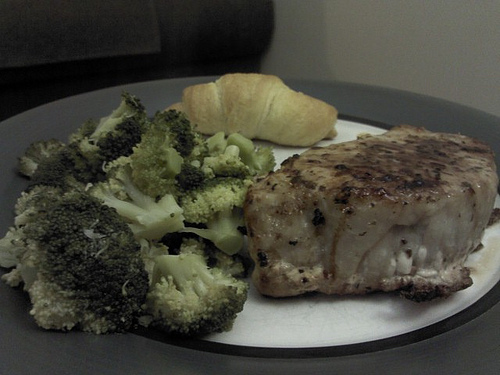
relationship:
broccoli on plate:
[15, 123, 235, 320] [25, 114, 79, 138]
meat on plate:
[269, 143, 456, 269] [25, 114, 79, 138]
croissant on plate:
[189, 89, 321, 145] [25, 114, 79, 138]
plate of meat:
[25, 114, 79, 138] [252, 124, 500, 304]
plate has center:
[25, 114, 79, 138] [274, 310, 342, 335]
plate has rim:
[25, 114, 79, 138] [355, 91, 417, 115]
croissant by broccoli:
[189, 89, 321, 145] [15, 123, 235, 320]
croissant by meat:
[189, 89, 321, 145] [269, 143, 456, 269]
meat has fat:
[269, 143, 456, 269] [269, 211, 389, 273]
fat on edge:
[269, 211, 389, 273] [247, 196, 295, 297]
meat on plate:
[252, 124, 500, 304] [25, 114, 79, 138]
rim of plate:
[355, 91, 417, 115] [25, 114, 79, 138]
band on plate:
[282, 343, 344, 362] [25, 114, 79, 138]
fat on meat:
[269, 211, 389, 273] [269, 143, 456, 269]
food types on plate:
[65, 111, 356, 249] [25, 114, 79, 138]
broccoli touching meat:
[15, 123, 235, 320] [269, 143, 456, 269]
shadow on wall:
[288, 52, 323, 78] [354, 43, 415, 59]